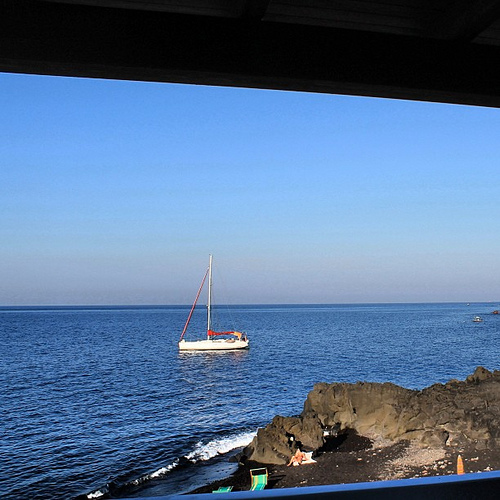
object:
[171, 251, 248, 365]
boat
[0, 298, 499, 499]
water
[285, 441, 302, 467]
person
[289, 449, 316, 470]
towel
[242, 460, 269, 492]
beach chair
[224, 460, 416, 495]
soil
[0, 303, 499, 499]
ripples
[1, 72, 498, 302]
blue sky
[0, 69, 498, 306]
white clouds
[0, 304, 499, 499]
waves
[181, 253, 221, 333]
mast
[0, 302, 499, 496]
ocean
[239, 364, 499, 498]
rocks